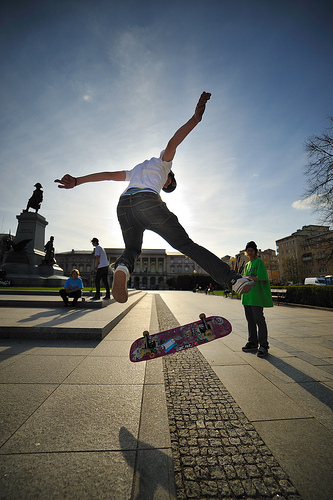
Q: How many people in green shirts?
A: One.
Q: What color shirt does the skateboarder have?
A: White.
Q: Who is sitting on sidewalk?
A: Person in blue shirt.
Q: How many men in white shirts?
A: Two.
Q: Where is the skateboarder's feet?
A: In air.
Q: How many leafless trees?
A: One.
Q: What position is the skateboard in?
A: Upside down.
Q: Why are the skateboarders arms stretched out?
A: For balance.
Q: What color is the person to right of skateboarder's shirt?
A: Green.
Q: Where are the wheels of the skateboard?
A: On bottom.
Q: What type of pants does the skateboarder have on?
A: Blue jeans.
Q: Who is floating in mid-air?
A: The skateboarder.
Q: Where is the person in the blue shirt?
A: Sitting on the steps.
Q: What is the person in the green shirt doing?
A: Watching the skateboarder.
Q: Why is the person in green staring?
A: The skateboarder is doing tricks.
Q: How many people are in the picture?
A: 4.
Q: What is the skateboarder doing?
A: Jumping.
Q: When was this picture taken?
A: Afternoon.